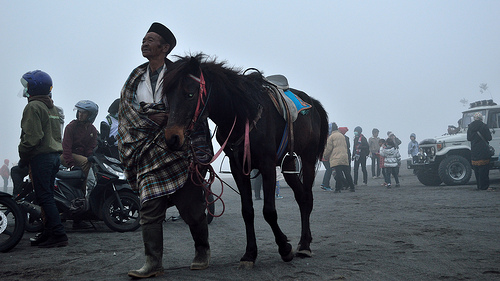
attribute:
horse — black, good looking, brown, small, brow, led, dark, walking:
[157, 50, 332, 268]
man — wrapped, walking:
[114, 22, 232, 279]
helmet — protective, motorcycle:
[21, 69, 53, 96]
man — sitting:
[59, 96, 106, 170]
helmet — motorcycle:
[74, 99, 100, 123]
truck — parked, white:
[406, 89, 500, 191]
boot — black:
[128, 222, 168, 278]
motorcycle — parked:
[18, 154, 151, 235]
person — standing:
[378, 138, 404, 188]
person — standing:
[324, 117, 355, 197]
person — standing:
[352, 124, 369, 187]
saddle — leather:
[261, 72, 298, 120]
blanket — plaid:
[120, 57, 205, 207]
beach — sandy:
[6, 150, 500, 256]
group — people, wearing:
[320, 118, 500, 195]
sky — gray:
[4, 2, 493, 274]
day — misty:
[4, 2, 494, 275]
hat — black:
[147, 22, 179, 49]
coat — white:
[380, 144, 400, 171]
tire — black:
[437, 151, 475, 183]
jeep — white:
[405, 93, 500, 199]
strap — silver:
[280, 155, 305, 172]